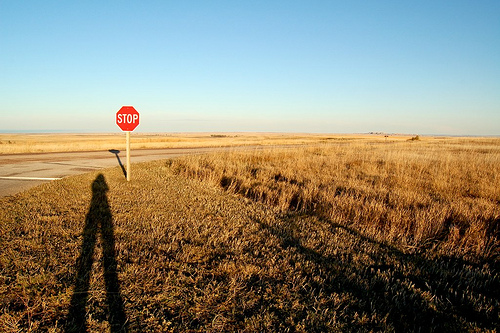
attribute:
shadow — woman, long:
[68, 169, 142, 330]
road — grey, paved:
[1, 148, 357, 191]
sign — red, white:
[109, 100, 144, 134]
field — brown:
[172, 140, 499, 330]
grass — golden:
[226, 131, 495, 275]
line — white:
[2, 164, 54, 185]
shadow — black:
[150, 238, 279, 292]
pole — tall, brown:
[117, 125, 137, 185]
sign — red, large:
[113, 105, 142, 128]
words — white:
[115, 113, 140, 125]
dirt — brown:
[8, 147, 178, 161]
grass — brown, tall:
[170, 129, 497, 289]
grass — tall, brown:
[175, 140, 498, 281]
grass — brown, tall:
[173, 145, 498, 266]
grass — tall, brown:
[166, 142, 498, 292]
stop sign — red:
[113, 105, 143, 130]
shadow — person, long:
[61, 169, 137, 332]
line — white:
[8, 164, 55, 184]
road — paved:
[2, 151, 200, 240]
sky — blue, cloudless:
[2, 5, 498, 150]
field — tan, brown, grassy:
[154, 221, 434, 308]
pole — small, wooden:
[124, 129, 135, 180]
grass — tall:
[148, 210, 185, 256]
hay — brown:
[336, 172, 410, 252]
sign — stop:
[111, 101, 142, 132]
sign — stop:
[114, 100, 137, 168]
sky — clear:
[146, 17, 200, 67]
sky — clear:
[205, 32, 278, 89]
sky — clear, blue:
[304, 35, 387, 93]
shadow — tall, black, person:
[72, 170, 123, 330]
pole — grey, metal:
[122, 130, 135, 177]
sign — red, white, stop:
[113, 103, 143, 130]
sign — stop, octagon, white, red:
[116, 103, 140, 131]